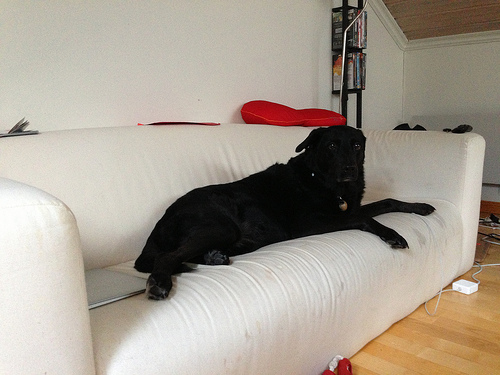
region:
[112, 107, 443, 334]
Black dog on the couch.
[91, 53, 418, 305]
dog on the couch.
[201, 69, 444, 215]
Red pillow on the couch.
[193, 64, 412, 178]
Red pillow on the white couch.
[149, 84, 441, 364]
White couch with black dog.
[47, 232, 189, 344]
Laptop on the couch.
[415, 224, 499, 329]
Wires on the floor.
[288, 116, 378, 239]
Dog with a collar.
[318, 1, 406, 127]
DVDs in the background.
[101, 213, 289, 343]
Feet of the dog.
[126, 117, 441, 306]
black dog on couch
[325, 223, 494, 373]
tan hardwood floors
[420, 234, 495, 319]
white power cord on floor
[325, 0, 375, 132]
black shelf on wall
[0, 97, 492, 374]
white couch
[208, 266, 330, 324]
wrinkles on seat of couch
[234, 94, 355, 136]
red pillow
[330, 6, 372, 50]
dvd's on shelf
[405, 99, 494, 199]
black shadow on wall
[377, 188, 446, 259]
dog paws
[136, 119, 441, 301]
LARGE BLACK DOG ON CO UCH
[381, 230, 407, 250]
PAW OF BLACK DOG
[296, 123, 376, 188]
HEAD OF BLACK DOG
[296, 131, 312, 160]
EAR OF BLACK DOG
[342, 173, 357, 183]
NOSE OF BLACK DOG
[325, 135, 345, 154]
EYE OF BLACK DOG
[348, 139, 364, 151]
EYE OF BLACK DOG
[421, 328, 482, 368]
PART OF BROWN WOODEN FLOOR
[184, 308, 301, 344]
PART OF WHITE CO UCH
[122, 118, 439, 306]
black dog laying down on sofa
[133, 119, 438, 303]
black dog resting on white couch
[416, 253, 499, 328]
wire and box on wooden floor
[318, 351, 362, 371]
red object on floor next to white sofa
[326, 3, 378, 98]
video's on shelf next to sofa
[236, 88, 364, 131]
red pillow laying on white sofa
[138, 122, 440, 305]
black dog in front of red pillow on sofa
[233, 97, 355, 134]
red pillow above black dog on white sofa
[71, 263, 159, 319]
silver object on sofa behind dog paw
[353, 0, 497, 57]
white wall trim on ceiling of room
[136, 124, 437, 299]
large black labrador retriever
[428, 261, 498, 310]
computer ac wires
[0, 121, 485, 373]
large black dog on large white sofa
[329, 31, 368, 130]
open bookcase attached to wall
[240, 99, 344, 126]
orange rectangular pillow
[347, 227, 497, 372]
light wood flooring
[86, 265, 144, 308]
silver Apple Mac laptop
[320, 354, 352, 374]
rubber and white rope dog toy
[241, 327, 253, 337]
dog fur on sofa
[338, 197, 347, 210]
dog tags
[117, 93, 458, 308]
black dog on couch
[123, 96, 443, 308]
black dog on couch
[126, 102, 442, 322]
black dog on couch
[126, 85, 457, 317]
black dog on couch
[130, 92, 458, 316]
black dog on couch